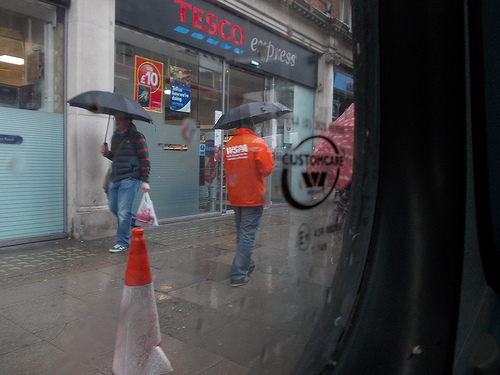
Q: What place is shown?
A: It is a sidewalk.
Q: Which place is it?
A: It is a sidewalk.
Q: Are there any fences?
A: No, there are no fences.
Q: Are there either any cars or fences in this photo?
A: No, there are no fences or cars.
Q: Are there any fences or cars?
A: No, there are no fences or cars.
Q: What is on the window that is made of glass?
A: The sign is on the window.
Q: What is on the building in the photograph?
A: The sign is on the building.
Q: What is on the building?
A: The sign is on the building.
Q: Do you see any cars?
A: No, there are no cars.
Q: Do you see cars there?
A: No, there are no cars.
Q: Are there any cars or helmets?
A: No, there are no cars or helmets.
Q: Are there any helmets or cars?
A: No, there are no cars or helmets.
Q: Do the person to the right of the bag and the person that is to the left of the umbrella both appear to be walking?
A: Yes, both the person and the person are walking.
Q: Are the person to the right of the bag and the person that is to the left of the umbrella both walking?
A: Yes, both the person and the person are walking.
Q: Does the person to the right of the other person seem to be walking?
A: Yes, the person is walking.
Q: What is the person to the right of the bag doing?
A: The person is walking.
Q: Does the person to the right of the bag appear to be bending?
A: No, the person is walking.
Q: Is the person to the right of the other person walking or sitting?
A: The person is walking.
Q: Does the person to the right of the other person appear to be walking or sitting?
A: The person is walking.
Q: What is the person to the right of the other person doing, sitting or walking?
A: The person is walking.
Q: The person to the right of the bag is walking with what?
A: The person is walking with an umbrella.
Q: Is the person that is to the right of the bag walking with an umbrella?
A: Yes, the person is walking with an umbrella.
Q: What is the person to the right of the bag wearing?
A: The person is wearing a jacket.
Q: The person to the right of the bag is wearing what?
A: The person is wearing a jacket.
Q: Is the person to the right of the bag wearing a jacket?
A: Yes, the person is wearing a jacket.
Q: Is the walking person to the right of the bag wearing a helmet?
A: No, the person is wearing a jacket.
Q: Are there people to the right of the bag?
A: Yes, there is a person to the right of the bag.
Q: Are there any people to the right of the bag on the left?
A: Yes, there is a person to the right of the bag.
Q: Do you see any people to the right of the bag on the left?
A: Yes, there is a person to the right of the bag.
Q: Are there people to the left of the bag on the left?
A: No, the person is to the right of the bag.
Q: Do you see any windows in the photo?
A: Yes, there is a window.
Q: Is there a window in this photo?
A: Yes, there is a window.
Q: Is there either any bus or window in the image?
A: Yes, there is a window.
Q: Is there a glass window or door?
A: Yes, there is a glass window.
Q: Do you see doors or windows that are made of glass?
A: Yes, the window is made of glass.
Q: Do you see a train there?
A: No, there are no trains.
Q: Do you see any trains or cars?
A: No, there are no trains or cars.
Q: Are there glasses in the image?
A: No, there are no glasses.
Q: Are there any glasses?
A: No, there are no glasses.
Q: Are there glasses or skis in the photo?
A: No, there are no glasses or skis.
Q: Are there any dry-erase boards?
A: No, there are no dry-erase boards.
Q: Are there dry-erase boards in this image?
A: No, there are no dry-erase boards.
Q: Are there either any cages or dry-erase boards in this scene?
A: No, there are no dry-erase boards or cages.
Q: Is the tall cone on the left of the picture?
A: Yes, the safety cone is on the left of the image.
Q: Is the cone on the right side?
A: No, the cone is on the left of the image.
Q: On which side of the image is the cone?
A: The cone is on the left of the image.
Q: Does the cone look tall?
A: Yes, the cone is tall.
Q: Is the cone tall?
A: Yes, the cone is tall.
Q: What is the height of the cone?
A: The cone is tall.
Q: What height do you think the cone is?
A: The cone is tall.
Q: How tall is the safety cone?
A: The safety cone is tall.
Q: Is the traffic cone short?
A: No, the traffic cone is tall.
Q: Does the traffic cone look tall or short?
A: The traffic cone is tall.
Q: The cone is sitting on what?
A: The cone is sitting on the sidewalk.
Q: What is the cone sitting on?
A: The cone is sitting on the sidewalk.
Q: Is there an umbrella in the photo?
A: Yes, there is an umbrella.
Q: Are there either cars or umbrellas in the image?
A: Yes, there is an umbrella.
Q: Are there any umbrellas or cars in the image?
A: Yes, there is an umbrella.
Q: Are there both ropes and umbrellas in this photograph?
A: No, there is an umbrella but no ropes.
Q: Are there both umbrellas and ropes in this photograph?
A: No, there is an umbrella but no ropes.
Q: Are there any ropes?
A: No, there are no ropes.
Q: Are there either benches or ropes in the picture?
A: No, there are no ropes or benches.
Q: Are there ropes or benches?
A: No, there are no ropes or benches.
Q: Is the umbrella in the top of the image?
A: Yes, the umbrella is in the top of the image.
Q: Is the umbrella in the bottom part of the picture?
A: No, the umbrella is in the top of the image.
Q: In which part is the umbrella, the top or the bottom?
A: The umbrella is in the top of the image.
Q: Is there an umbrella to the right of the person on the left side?
A: Yes, there is an umbrella to the right of the person.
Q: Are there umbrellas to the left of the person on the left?
A: No, the umbrella is to the right of the person.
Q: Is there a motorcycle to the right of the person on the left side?
A: No, there is an umbrella to the right of the person.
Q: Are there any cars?
A: No, there are no cars.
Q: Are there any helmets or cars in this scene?
A: No, there are no cars or helmets.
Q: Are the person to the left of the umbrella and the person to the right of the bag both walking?
A: Yes, both the person and the person are walking.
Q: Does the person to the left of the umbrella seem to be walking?
A: Yes, the person is walking.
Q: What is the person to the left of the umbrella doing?
A: The person is walking.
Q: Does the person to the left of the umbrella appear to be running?
A: No, the person is walking.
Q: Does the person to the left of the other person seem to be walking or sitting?
A: The person is walking.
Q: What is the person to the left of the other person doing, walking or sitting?
A: The person is walking.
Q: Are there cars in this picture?
A: No, there are no cars.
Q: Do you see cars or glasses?
A: No, there are no cars or glasses.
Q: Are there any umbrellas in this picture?
A: Yes, there is an umbrella.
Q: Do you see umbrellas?
A: Yes, there is an umbrella.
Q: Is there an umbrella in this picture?
A: Yes, there is an umbrella.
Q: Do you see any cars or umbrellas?
A: Yes, there is an umbrella.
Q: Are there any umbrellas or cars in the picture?
A: Yes, there is an umbrella.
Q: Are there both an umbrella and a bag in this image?
A: Yes, there are both an umbrella and a bag.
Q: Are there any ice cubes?
A: No, there are no ice cubes.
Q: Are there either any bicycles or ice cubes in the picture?
A: No, there are no ice cubes or bicycles.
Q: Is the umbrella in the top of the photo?
A: Yes, the umbrella is in the top of the image.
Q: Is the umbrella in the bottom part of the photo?
A: No, the umbrella is in the top of the image.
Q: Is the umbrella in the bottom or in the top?
A: The umbrella is in the top of the image.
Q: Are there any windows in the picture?
A: Yes, there is a window.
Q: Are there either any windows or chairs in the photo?
A: Yes, there is a window.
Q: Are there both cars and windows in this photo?
A: No, there is a window but no cars.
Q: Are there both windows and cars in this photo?
A: No, there is a window but no cars.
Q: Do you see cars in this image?
A: No, there are no cars.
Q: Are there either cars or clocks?
A: No, there are no cars or clocks.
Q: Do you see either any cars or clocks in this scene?
A: No, there are no cars or clocks.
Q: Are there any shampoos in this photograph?
A: No, there are no shampoos.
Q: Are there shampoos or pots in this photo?
A: No, there are no shampoos or pots.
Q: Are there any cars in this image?
A: No, there are no cars.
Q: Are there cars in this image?
A: No, there are no cars.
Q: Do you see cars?
A: No, there are no cars.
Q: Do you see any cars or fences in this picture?
A: No, there are no cars or fences.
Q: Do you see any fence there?
A: No, there are no fences.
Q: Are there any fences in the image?
A: No, there are no fences.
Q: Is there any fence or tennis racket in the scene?
A: No, there are no fences or rackets.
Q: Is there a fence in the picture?
A: No, there are no fences.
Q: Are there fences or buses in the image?
A: No, there are no fences or buses.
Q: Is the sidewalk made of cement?
A: Yes, the sidewalk is made of cement.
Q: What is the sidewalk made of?
A: The sidewalk is made of concrete.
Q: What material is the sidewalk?
A: The sidewalk is made of concrete.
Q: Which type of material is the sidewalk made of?
A: The sidewalk is made of concrete.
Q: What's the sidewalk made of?
A: The sidewalk is made of concrete.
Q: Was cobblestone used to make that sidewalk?
A: No, the sidewalk is made of concrete.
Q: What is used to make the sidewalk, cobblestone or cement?
A: The sidewalk is made of cement.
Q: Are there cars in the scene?
A: No, there are no cars.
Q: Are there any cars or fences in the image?
A: No, there are no cars or fences.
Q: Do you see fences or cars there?
A: No, there are no cars or fences.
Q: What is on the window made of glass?
A: The sign is on the window.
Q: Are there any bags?
A: Yes, there is a bag.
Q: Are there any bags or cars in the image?
A: Yes, there is a bag.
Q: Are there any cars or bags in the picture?
A: Yes, there is a bag.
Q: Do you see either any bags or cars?
A: Yes, there is a bag.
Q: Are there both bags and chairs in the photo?
A: No, there is a bag but no chairs.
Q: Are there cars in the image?
A: No, there are no cars.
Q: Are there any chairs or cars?
A: No, there are no cars or chairs.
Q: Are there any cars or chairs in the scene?
A: No, there are no cars or chairs.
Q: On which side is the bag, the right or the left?
A: The bag is on the left of the image.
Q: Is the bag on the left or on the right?
A: The bag is on the left of the image.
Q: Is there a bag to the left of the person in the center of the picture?
A: Yes, there is a bag to the left of the person.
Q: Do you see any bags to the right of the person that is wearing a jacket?
A: No, the bag is to the left of the person.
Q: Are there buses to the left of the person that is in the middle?
A: No, there is a bag to the left of the person.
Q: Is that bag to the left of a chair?
A: No, the bag is to the left of a person.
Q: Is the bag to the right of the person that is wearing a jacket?
A: No, the bag is to the left of the person.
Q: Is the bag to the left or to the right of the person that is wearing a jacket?
A: The bag is to the left of the person.